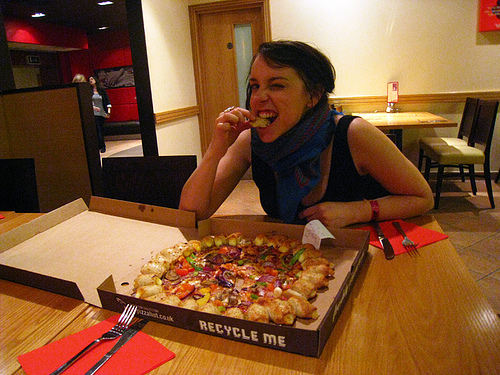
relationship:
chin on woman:
[254, 126, 279, 143] [178, 40, 434, 228]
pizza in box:
[130, 230, 335, 329] [0, 194, 372, 362]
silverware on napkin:
[50, 303, 145, 370] [121, 347, 143, 359]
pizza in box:
[135, 230, 336, 322] [0, 194, 368, 357]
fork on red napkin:
[393, 217, 419, 254] [361, 211, 448, 254]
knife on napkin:
[373, 218, 395, 260] [14, 313, 175, 375]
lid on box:
[0, 194, 195, 302] [0, 194, 368, 357]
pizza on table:
[130, 230, 335, 329] [2, 176, 483, 368]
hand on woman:
[199, 103, 260, 163] [178, 40, 434, 228]